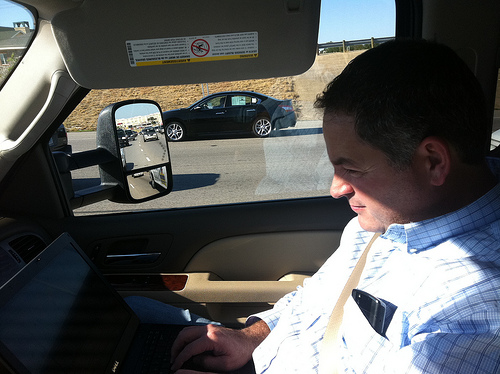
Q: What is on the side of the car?
A: A mirror.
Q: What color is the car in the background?
A: Black.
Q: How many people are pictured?
A: One.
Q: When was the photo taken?
A: Daytime.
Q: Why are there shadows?
A: It is sunny.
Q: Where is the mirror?
A: On the side of the car.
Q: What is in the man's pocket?
A: His phone.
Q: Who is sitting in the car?
A: The man.